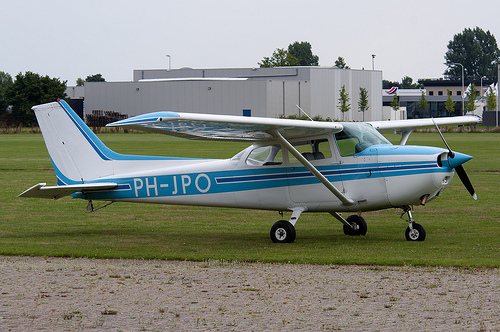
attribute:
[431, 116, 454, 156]
propellors — black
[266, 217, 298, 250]
wheel — black, round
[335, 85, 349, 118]
trees — small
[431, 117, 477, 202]
propeller — black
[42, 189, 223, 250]
grass — green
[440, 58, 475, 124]
light — tall, metal, security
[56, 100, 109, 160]
stripe — blue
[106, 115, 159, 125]
stripe — blue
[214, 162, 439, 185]
stripe — blue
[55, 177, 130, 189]
stripe — blue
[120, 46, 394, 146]
building — white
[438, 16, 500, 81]
leaves — green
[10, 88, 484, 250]
airplane — blue, white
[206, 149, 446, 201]
stripe — small